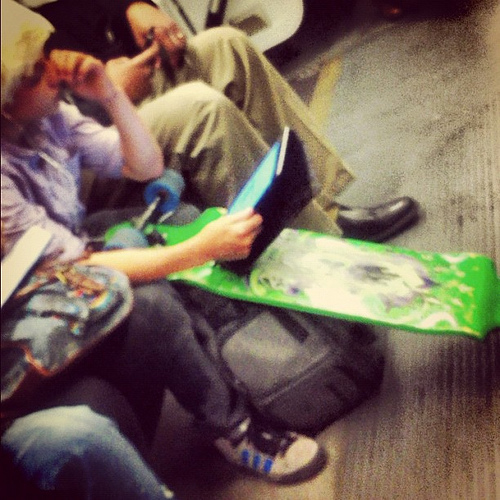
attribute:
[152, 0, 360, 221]
pants — tan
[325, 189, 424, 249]
shoe — black, leather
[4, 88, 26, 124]
earphones — white 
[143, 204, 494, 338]
skateboard — green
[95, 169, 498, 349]
skateboard — green, blue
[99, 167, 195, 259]
wheels — blue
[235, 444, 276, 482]
stripes — blue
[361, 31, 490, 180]
floor — gray, brown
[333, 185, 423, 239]
loafer — brown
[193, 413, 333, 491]
shoes — white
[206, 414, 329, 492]
shoe — white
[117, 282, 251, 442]
jeans — black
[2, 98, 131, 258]
shirt — white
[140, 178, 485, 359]
skateboard — green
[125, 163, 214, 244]
wheels — blue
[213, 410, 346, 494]
shoes — white, blue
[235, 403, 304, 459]
laces — black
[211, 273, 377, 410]
backpack — black, grey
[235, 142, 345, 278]
tablet cover — black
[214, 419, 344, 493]
shoes — blue, striped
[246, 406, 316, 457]
shoelaces — black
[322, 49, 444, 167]
floor — dirty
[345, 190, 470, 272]
shoes — black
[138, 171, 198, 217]
wheels — blue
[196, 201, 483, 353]
skateboard — bright green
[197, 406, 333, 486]
shoe — white, athletic, blue, striped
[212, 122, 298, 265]
ipad — open running 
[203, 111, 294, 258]
computer — tablet 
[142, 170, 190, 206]
wheel —  blue skateboard 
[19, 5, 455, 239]
slacks — khaki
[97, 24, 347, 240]
pants — beige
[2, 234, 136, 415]
skateboard — colorful